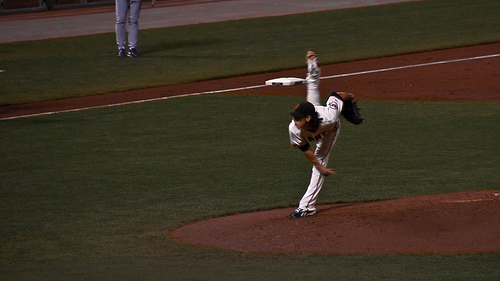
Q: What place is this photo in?
A: It is at the field.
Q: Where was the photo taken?
A: It was taken at the field.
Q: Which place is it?
A: It is a field.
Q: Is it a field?
A: Yes, it is a field.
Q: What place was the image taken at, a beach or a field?
A: It was taken at a field.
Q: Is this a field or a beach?
A: It is a field.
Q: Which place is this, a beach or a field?
A: It is a field.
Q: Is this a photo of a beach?
A: No, the picture is showing a field.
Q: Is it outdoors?
A: Yes, it is outdoors.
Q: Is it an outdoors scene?
A: Yes, it is outdoors.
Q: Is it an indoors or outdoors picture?
A: It is outdoors.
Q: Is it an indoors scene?
A: No, it is outdoors.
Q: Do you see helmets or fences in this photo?
A: No, there are no fences or helmets.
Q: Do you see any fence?
A: No, there are no fences.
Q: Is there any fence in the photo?
A: No, there are no fences.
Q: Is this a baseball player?
A: Yes, this is a baseball player.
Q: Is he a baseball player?
A: Yes, this is a baseball player.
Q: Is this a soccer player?
A: No, this is a baseball player.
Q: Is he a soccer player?
A: No, this is a baseball player.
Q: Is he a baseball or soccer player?
A: This is a baseball player.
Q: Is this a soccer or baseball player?
A: This is a baseball player.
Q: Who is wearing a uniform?
A: The player is wearing a uniform.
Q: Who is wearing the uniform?
A: The player is wearing a uniform.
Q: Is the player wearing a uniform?
A: Yes, the player is wearing a uniform.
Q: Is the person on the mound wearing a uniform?
A: Yes, the player is wearing a uniform.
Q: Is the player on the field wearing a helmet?
A: No, the player is wearing a uniform.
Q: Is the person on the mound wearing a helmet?
A: No, the player is wearing a uniform.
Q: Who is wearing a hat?
A: The player is wearing a hat.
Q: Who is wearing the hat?
A: The player is wearing a hat.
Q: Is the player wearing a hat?
A: Yes, the player is wearing a hat.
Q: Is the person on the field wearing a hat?
A: Yes, the player is wearing a hat.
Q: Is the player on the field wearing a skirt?
A: No, the player is wearing a hat.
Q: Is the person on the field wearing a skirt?
A: No, the player is wearing a hat.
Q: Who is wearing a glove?
A: The player is wearing a glove.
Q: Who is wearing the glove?
A: The player is wearing a glove.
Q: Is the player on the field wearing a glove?
A: Yes, the player is wearing a glove.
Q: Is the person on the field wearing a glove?
A: Yes, the player is wearing a glove.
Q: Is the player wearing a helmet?
A: No, the player is wearing a glove.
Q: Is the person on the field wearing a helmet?
A: No, the player is wearing a glove.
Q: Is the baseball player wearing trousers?
A: Yes, the player is wearing trousers.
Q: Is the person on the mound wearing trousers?
A: Yes, the player is wearing trousers.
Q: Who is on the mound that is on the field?
A: The player is on the mound.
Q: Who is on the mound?
A: The player is on the mound.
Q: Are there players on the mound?
A: Yes, there is a player on the mound.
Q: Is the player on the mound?
A: Yes, the player is on the mound.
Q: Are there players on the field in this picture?
A: Yes, there is a player on the field.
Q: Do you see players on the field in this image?
A: Yes, there is a player on the field.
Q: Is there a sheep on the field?
A: No, there is a player on the field.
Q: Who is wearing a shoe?
A: The player is wearing a shoe.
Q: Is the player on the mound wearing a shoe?
A: Yes, the player is wearing a shoe.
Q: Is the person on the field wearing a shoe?
A: Yes, the player is wearing a shoe.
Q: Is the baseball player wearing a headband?
A: No, the player is wearing a shoe.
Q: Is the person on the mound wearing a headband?
A: No, the player is wearing a shoe.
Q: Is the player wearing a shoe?
A: Yes, the player is wearing a shoe.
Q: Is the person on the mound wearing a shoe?
A: Yes, the player is wearing a shoe.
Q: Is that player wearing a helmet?
A: No, the player is wearing a shoe.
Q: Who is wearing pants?
A: The player is wearing pants.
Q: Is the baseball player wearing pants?
A: Yes, the player is wearing pants.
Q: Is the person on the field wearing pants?
A: Yes, the player is wearing pants.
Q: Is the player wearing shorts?
A: No, the player is wearing pants.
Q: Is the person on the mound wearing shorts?
A: No, the player is wearing pants.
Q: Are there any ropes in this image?
A: No, there are no ropes.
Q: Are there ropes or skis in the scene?
A: No, there are no ropes or skis.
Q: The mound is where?
A: The mound is on the field.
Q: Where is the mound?
A: The mound is on the field.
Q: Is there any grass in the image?
A: Yes, there is grass.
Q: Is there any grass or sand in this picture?
A: Yes, there is grass.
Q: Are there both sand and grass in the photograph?
A: No, there is grass but no sand.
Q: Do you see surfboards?
A: No, there are no surfboards.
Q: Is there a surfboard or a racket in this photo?
A: No, there are no surfboards or rackets.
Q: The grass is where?
A: The grass is on the field.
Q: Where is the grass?
A: The grass is on the field.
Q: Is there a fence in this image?
A: No, there are no fences.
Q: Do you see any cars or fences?
A: No, there are no fences or cars.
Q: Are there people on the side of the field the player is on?
A: Yes, there is a person on the side of the field.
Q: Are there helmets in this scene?
A: No, there are no helmets.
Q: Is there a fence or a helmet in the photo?
A: No, there are no helmets or fences.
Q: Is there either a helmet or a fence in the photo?
A: No, there are no helmets or fences.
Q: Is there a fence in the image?
A: No, there are no fences.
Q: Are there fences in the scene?
A: No, there are no fences.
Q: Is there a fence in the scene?
A: No, there are no fences.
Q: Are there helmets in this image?
A: No, there are no helmets.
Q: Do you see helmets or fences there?
A: No, there are no helmets or fences.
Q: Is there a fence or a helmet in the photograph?
A: No, there are no helmets or fences.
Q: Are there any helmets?
A: No, there are no helmets.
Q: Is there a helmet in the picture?
A: No, there are no helmets.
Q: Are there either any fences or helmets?
A: No, there are no helmets or fences.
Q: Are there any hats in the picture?
A: Yes, there is a hat.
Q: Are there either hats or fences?
A: Yes, there is a hat.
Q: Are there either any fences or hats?
A: Yes, there is a hat.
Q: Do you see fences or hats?
A: Yes, there is a hat.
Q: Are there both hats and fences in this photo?
A: No, there is a hat but no fences.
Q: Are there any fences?
A: No, there are no fences.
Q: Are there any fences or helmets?
A: No, there are no fences or helmets.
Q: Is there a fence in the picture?
A: No, there are no fences.